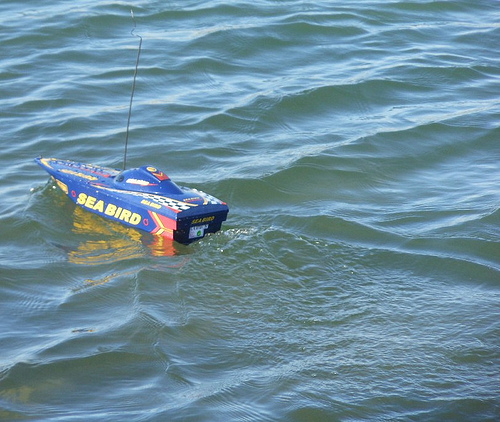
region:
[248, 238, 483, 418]
this is the water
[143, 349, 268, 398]
the water is blue in color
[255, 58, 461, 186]
the water is wavy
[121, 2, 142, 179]
this is an aerial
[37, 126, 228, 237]
this is a toy boat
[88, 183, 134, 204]
the toy is blue in color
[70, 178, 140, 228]
the toy has some writings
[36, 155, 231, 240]
the toy boat is in motion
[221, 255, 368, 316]
there are some ripples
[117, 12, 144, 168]
the aerial is long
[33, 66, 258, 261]
toy boat floating on water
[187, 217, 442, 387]
texture on water's surface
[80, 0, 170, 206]
long wire bent near top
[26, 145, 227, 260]
blue boat with colorful designs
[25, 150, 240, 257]
name of boat in yellow print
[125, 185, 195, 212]
black and white checkerboard in corner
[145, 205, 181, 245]
yellow arrow on red blocks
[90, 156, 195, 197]
curved section on top of boat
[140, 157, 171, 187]
figure on top of raised panel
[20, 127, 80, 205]
yellow curve at boat tip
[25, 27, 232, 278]
a small boat is on the water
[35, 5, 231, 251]
the boat is a toy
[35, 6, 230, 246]
the boat is radio controlled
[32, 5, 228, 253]
the toy is a Formula One race boat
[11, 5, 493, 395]
the water has large waves for the boat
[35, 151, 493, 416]
the race boat is leaving a wake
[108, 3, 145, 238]
the radio controlled antenna on the boat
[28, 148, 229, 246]
the boat's name is on its side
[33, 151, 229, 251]
the boat is blue with red and yellow stripes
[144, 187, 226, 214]
two checkered flags are painted over the engine room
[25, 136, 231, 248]
the toy boat is floating on water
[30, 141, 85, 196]
the boat has sharp head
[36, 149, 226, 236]
the boat is blue in color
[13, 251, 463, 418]
the water has small waves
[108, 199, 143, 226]
bird is written on the the boat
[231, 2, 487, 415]
the water is colorless in color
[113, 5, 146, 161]
the toy boat has an antennae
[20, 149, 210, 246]
the toy boat is made of plastic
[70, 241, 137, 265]
this is the toy boats reflection on the water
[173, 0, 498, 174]
A large body of water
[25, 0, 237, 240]
A colorful toy boat in the water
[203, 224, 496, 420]
Ripples in the water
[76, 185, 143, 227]
The words Sea Bird painted in yellow on the side of the boat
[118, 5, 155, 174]
A silver metal pole sticking up out of the boat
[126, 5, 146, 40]
The bent silver tip of the pole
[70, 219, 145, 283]
The reflection of the boat in the water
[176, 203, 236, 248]
The back of the boat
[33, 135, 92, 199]
The pointed tip of the boat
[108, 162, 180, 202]
The small mostly blue shape on the top of the boat